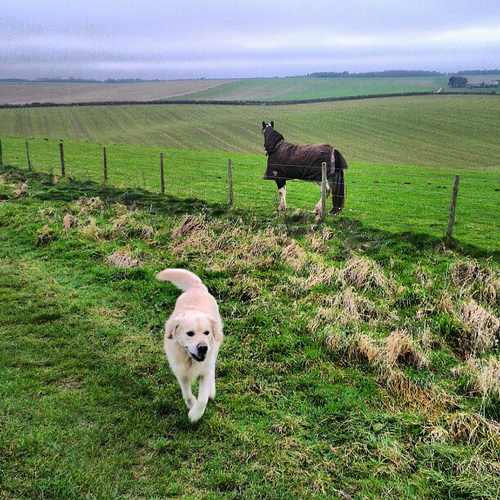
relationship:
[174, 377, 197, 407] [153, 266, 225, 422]
leg of dog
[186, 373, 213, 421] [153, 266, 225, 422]
leg of dog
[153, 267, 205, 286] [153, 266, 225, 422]
tail of dog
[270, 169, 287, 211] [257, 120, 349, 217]
legs of horse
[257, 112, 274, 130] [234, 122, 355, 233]
ears of horse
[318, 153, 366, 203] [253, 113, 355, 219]
tail of horse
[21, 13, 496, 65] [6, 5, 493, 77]
clouds in sky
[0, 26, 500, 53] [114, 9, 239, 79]
clouds in sky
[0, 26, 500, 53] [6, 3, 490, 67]
clouds in sky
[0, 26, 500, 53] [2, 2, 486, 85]
clouds in sky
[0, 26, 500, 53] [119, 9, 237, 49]
clouds in sky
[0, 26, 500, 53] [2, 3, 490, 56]
clouds in sky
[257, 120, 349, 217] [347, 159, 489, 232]
horse standing in pasture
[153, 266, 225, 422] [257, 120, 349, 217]
dog near horse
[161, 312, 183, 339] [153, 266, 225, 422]
ear of dog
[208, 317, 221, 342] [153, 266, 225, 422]
ear of dog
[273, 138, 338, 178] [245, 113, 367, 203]
blanket on horse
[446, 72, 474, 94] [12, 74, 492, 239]
tree in pasture